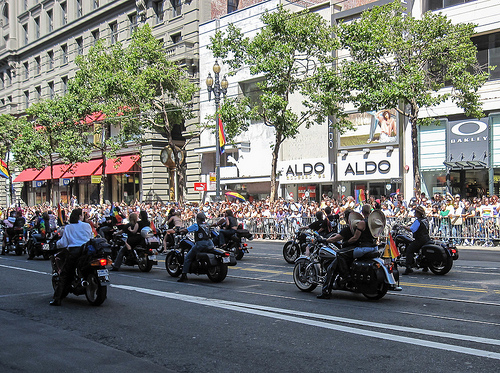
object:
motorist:
[208, 212, 226, 248]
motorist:
[21, 216, 42, 261]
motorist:
[96, 212, 114, 236]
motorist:
[0, 211, 15, 249]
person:
[297, 209, 325, 250]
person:
[334, 205, 380, 282]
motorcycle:
[281, 225, 311, 260]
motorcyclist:
[46, 209, 98, 309]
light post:
[206, 63, 229, 208]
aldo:
[342, 159, 391, 176]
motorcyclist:
[107, 213, 139, 273]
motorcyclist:
[294, 210, 357, 302]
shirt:
[54, 222, 96, 253]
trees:
[331, 1, 487, 206]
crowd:
[0, 193, 496, 245]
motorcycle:
[386, 224, 458, 278]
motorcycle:
[107, 231, 157, 271]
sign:
[273, 160, 333, 185]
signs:
[336, 149, 400, 181]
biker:
[392, 208, 429, 276]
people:
[216, 210, 239, 249]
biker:
[167, 212, 220, 280]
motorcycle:
[46, 232, 111, 307]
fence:
[242, 215, 498, 240]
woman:
[123, 207, 151, 255]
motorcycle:
[280, 223, 356, 267]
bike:
[47, 230, 113, 307]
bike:
[164, 228, 229, 282]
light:
[96, 256, 106, 269]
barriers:
[148, 216, 496, 237]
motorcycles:
[385, 223, 459, 279]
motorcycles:
[1, 207, 64, 253]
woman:
[334, 203, 376, 283]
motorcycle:
[291, 226, 403, 299]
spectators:
[252, 200, 262, 210]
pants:
[180, 240, 212, 275]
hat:
[367, 209, 385, 239]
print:
[335, 111, 397, 146]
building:
[196, 0, 413, 210]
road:
[1, 240, 498, 371]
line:
[0, 262, 218, 307]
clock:
[168, 142, 185, 169]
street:
[1, 236, 499, 371]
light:
[219, 251, 233, 257]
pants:
[51, 247, 85, 301]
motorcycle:
[390, 224, 459, 276]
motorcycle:
[212, 227, 245, 262]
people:
[274, 208, 286, 238]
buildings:
[0, 0, 199, 212]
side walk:
[230, 226, 473, 256]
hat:
[345, 212, 366, 236]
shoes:
[43, 288, 68, 313]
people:
[164, 211, 186, 248]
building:
[412, 0, 499, 223]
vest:
[191, 221, 216, 244]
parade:
[2, 201, 498, 324]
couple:
[314, 203, 377, 302]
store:
[339, 146, 399, 202]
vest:
[410, 218, 429, 239]